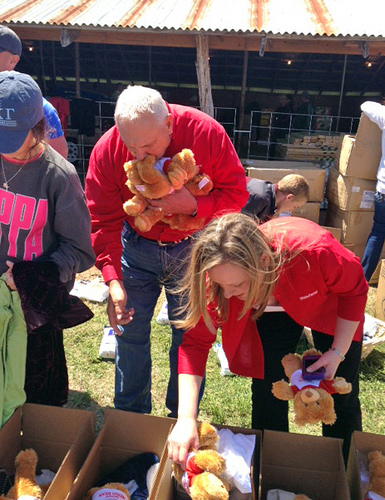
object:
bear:
[170, 417, 232, 499]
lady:
[166, 213, 370, 487]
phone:
[302, 354, 325, 380]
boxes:
[0, 404, 97, 499]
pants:
[250, 307, 362, 479]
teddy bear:
[270, 348, 353, 427]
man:
[84, 83, 248, 421]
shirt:
[176, 216, 371, 381]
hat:
[0, 69, 45, 154]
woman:
[0, 70, 97, 407]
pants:
[112, 220, 203, 418]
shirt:
[0, 140, 95, 287]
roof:
[0, 0, 384, 37]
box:
[331, 209, 376, 248]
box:
[325, 170, 376, 212]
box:
[333, 111, 384, 179]